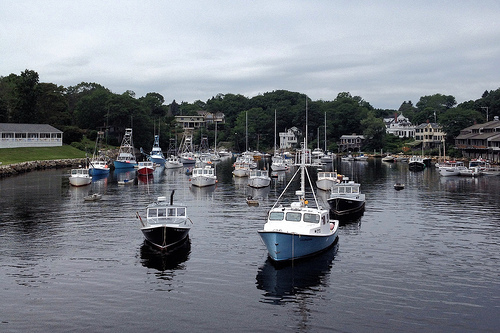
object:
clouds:
[0, 0, 497, 111]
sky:
[0, 0, 500, 112]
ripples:
[332, 252, 459, 329]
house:
[336, 132, 373, 153]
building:
[454, 116, 500, 164]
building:
[414, 123, 446, 149]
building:
[383, 112, 416, 138]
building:
[175, 110, 226, 130]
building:
[0, 122, 63, 149]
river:
[0, 154, 500, 333]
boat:
[394, 182, 405, 190]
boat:
[316, 165, 340, 190]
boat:
[164, 155, 183, 169]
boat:
[118, 172, 134, 185]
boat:
[381, 154, 395, 163]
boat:
[408, 156, 426, 172]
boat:
[137, 161, 154, 175]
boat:
[83, 192, 102, 201]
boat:
[245, 194, 259, 205]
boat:
[135, 190, 193, 248]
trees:
[224, 95, 273, 149]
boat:
[326, 176, 366, 215]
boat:
[256, 137, 339, 261]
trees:
[80, 85, 121, 139]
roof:
[453, 121, 500, 149]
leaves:
[236, 89, 293, 123]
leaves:
[59, 127, 82, 144]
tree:
[0, 69, 72, 124]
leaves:
[16, 69, 38, 89]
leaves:
[133, 101, 150, 116]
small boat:
[83, 194, 102, 201]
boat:
[69, 164, 93, 187]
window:
[269, 212, 283, 220]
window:
[286, 212, 301, 221]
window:
[303, 213, 320, 224]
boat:
[248, 163, 272, 189]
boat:
[114, 153, 137, 169]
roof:
[0, 124, 63, 133]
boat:
[191, 161, 217, 187]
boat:
[88, 157, 110, 176]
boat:
[179, 151, 196, 163]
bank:
[0, 153, 90, 178]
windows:
[148, 208, 185, 217]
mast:
[295, 137, 308, 207]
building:
[279, 126, 314, 149]